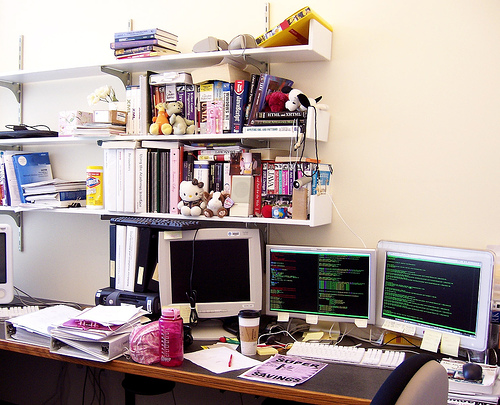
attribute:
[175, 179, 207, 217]
kitty — Hello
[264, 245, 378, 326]
screen — on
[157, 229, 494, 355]
screens — three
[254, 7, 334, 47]
box — yellow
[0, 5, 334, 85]
shelf — top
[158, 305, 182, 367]
bottle — pink, water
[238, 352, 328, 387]
ad — super savings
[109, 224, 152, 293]
binders — four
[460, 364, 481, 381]
mouse — black, computer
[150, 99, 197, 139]
animals — stuffed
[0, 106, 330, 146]
shelf — white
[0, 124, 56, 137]
shoes — pair of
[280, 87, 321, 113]
toy — black, white, snoopy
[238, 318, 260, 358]
cup — white, coffee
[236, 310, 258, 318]
lid — black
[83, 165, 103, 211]
container — yellow, clorox wipes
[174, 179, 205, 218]
kitty — white, stuffed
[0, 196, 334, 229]
shelf — white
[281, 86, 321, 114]
dog — black, white, stuffed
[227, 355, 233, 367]
pen — red, ink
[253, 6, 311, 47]
book — yellow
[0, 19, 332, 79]
shelf — top, white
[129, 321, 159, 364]
case — pink, white, makeup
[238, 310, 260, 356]
cup — carryout, coffee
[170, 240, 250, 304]
screen — monitor, computer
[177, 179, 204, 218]
animal — white, stuffed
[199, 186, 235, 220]
animal — brown, white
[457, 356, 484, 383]
mouse — black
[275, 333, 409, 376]
keyboard — white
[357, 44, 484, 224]
wall — white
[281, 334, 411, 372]
keyboard — white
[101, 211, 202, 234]
keyboard — black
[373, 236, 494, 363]
screen — on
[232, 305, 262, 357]
drink — hot, dark brown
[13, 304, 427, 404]
table — brown